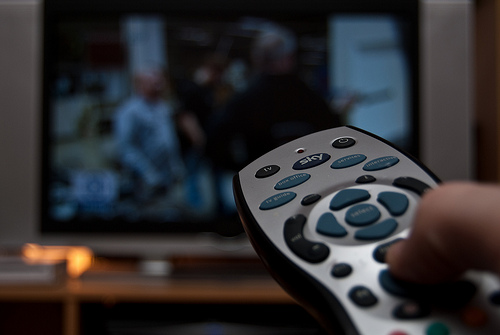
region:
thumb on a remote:
[223, 110, 490, 334]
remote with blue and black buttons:
[228, 113, 396, 330]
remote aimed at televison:
[18, 13, 390, 333]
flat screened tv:
[18, 7, 228, 245]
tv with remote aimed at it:
[28, 6, 410, 333]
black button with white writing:
[291, 151, 331, 169]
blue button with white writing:
[343, 198, 383, 226]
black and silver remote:
[224, 104, 397, 328]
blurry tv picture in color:
[49, 10, 231, 210]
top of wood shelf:
[4, 273, 284, 308]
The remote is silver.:
[232, 120, 489, 332]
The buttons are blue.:
[253, 171, 307, 209]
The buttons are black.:
[274, 205, 324, 270]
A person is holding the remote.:
[212, 115, 498, 299]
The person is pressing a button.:
[216, 120, 484, 327]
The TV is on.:
[38, 2, 425, 257]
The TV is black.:
[36, 6, 420, 256]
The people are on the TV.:
[102, 8, 329, 198]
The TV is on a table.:
[7, 12, 382, 333]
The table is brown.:
[6, 247, 316, 327]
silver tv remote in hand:
[221, 97, 439, 332]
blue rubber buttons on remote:
[310, 173, 406, 251]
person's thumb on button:
[341, 167, 498, 249]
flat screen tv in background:
[36, 1, 497, 248]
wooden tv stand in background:
[53, 250, 343, 333]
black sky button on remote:
[275, 141, 341, 184]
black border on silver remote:
[214, 175, 365, 333]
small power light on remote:
[284, 145, 309, 156]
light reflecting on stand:
[13, 244, 124, 294]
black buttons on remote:
[281, 220, 326, 281]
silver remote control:
[231, 123, 499, 333]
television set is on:
[36, 2, 418, 230]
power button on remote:
[331, 135, 356, 149]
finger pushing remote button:
[385, 174, 498, 288]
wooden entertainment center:
[0, 265, 298, 328]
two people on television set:
[115, 27, 307, 123]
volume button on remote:
[282, 211, 330, 264]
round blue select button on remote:
[344, 200, 381, 226]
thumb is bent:
[383, 179, 498, 287]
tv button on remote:
[254, 164, 281, 177]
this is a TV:
[7, 3, 469, 173]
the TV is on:
[67, 29, 390, 110]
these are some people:
[112, 61, 248, 157]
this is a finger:
[391, 183, 492, 281]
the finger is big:
[388, 181, 499, 275]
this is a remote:
[231, 127, 461, 333]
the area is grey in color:
[263, 208, 273, 227]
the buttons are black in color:
[282, 207, 337, 273]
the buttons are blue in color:
[316, 184, 412, 243]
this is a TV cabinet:
[114, 275, 231, 331]